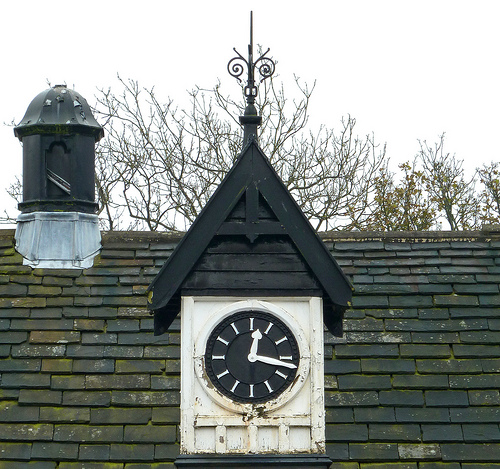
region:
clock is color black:
[193, 301, 310, 411]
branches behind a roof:
[0, 5, 499, 465]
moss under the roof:
[35, 350, 175, 436]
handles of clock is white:
[245, 325, 298, 376]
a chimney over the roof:
[8, 65, 114, 280]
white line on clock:
[247, 315, 254, 334]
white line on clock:
[262, 320, 272, 334]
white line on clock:
[273, 333, 289, 345]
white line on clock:
[278, 351, 293, 361]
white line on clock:
[273, 368, 287, 378]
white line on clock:
[263, 378, 271, 393]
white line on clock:
[248, 381, 255, 398]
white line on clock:
[228, 377, 238, 392]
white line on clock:
[215, 368, 228, 378]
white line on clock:
[209, 353, 227, 362]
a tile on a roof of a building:
[368, 423, 425, 440]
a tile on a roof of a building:
[321, 422, 370, 447]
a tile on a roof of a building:
[320, 443, 346, 460]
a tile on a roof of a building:
[340, 443, 385, 463]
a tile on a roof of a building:
[395, 437, 445, 462]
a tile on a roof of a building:
[435, 439, 499, 466]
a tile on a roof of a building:
[352, 405, 402, 427]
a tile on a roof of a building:
[423, 390, 474, 407]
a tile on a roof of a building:
[325, 388, 380, 408]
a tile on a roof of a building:
[121, 424, 183, 446]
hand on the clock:
[248, 329, 266, 346]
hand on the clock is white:
[249, 330, 268, 354]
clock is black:
[205, 309, 305, 404]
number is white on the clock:
[261, 379, 276, 396]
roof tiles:
[14, 348, 175, 462]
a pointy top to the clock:
[215, 16, 294, 144]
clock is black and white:
[184, 291, 319, 427]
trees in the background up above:
[327, 111, 477, 226]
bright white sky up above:
[95, 1, 460, 118]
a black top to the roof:
[16, 85, 110, 258]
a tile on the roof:
[351, 441, 395, 459]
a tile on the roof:
[149, 406, 178, 423]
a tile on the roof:
[121, 425, 175, 444]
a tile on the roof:
[84, 403, 159, 428]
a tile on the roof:
[81, 446, 114, 465]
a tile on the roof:
[104, 443, 146, 462]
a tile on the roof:
[23, 387, 68, 409]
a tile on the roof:
[43, 360, 73, 371]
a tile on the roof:
[65, 340, 107, 360]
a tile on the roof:
[81, 330, 123, 349]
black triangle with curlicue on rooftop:
[146, 5, 351, 333]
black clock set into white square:
[176, 291, 326, 453]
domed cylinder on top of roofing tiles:
[15, 83, 103, 330]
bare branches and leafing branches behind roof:
[5, 40, 497, 235]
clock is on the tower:
[205, 305, 300, 407]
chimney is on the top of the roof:
[8, 80, 107, 262]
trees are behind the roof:
[1, 42, 498, 232]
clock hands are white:
[244, 329, 294, 373]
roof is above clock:
[142, 7, 355, 339]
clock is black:
[206, 310, 300, 405]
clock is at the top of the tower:
[203, 307, 301, 401]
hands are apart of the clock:
[246, 326, 299, 371]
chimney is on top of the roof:
[9, 83, 106, 257]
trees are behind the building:
[6, 47, 498, 226]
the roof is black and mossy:
[1, 227, 498, 464]